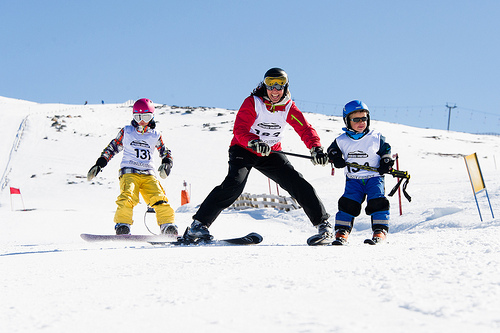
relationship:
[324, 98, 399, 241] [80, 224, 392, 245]
boy on skis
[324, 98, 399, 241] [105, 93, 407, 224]
boy in snowsuits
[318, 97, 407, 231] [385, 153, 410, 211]
boy holding pole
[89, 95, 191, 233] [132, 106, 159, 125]
girl wearing goggles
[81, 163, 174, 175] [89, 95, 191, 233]
gloves on girl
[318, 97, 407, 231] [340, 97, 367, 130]
boy wearing a helmet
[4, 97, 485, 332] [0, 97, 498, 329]
mountain covered in snow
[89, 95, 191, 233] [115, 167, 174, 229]
girl has yellow pants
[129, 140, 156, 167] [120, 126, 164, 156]
numbers on chest